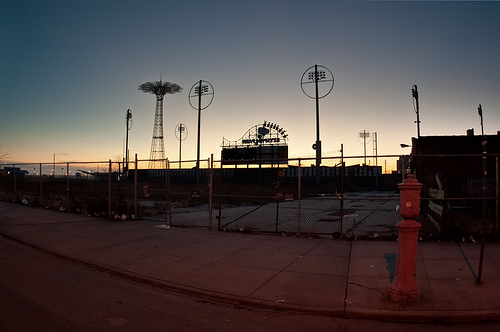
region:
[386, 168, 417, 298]
red fire hydrant on sidewalk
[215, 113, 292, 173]
large billboard in background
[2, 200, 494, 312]
sidewalk that fire hydrant is on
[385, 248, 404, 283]
shadow made by red fire hydrant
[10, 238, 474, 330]
street beside fire hydrant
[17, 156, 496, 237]
fencing running along sidewalk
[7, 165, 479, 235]
fenceposts holding up fencing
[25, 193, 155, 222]
trash along the fence line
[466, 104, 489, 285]
black pole next to fire hydrant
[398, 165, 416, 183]
top of red fire hydrant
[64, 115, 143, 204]
sunset is visible in the sky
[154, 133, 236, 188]
sunset is visible in the sky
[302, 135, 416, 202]
sunset is visible in the sky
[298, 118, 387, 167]
sunset is visible in the sky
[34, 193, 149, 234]
trash on the ground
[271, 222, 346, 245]
trash on the ground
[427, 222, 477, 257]
trash on the ground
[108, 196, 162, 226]
trash on the ground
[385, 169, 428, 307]
A red fire hydrant.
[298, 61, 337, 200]
A tall light pole.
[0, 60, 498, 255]
A fenced-off amusement park.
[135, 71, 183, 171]
A tall metal structure.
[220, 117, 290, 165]
A curvy shaped sign.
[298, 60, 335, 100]
A circular metal structure.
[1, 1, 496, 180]
The sun is setting.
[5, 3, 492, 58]
The sky is clear.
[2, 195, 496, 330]
The sidewalk is empty.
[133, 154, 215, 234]
The gate is slightly crooked.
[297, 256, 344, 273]
cement square on the sidewalk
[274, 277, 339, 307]
cement square on sidewalk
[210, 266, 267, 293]
cement square on sidewalk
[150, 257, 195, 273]
cement square on sidewalk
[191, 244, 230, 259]
cement square on sidewalk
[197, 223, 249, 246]
cement square on sidewalk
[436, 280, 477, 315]
cement square on sidewalk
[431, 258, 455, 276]
cement square on sidewalk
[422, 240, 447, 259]
cement square on sidewalk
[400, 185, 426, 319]
red fire hydrant on sidewalk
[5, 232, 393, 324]
curb along the street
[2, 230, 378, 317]
curb beside the sidewalk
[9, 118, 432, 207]
the horizon at sunset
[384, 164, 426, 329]
structure on side of road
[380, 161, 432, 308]
structure on side of street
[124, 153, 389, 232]
chain link fence by sidewalk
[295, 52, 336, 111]
circle in the air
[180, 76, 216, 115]
circle in the air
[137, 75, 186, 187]
tall tower with circular top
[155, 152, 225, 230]
gate of the fence